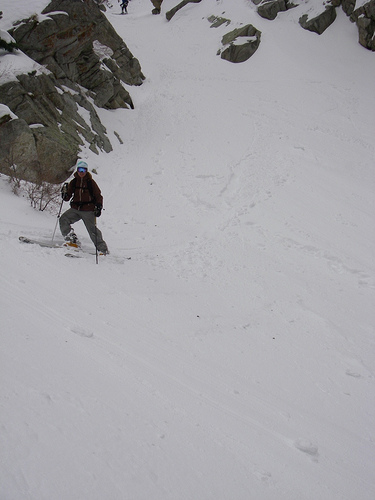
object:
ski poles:
[94, 214, 98, 264]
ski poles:
[51, 185, 66, 241]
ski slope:
[0, 0, 375, 500]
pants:
[59, 207, 108, 254]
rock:
[247, 0, 303, 21]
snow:
[0, 0, 375, 500]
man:
[59, 160, 109, 256]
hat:
[77, 160, 89, 167]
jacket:
[61, 171, 103, 211]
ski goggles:
[77, 167, 86, 173]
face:
[77, 167, 87, 178]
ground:
[2, 0, 373, 500]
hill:
[0, 0, 375, 260]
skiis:
[19, 226, 121, 268]